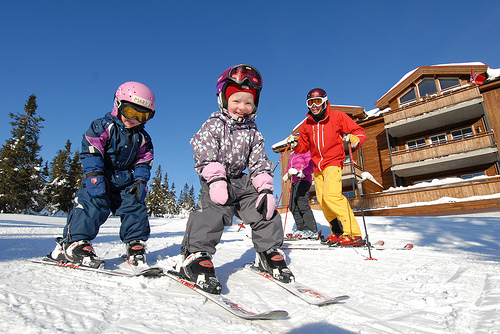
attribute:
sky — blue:
[285, 25, 385, 92]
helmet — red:
[304, 86, 329, 103]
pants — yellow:
[297, 147, 375, 247]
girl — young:
[52, 77, 157, 267]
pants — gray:
[185, 169, 280, 254]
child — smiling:
[176, 65, 295, 292]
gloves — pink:
[201, 159, 278, 221]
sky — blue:
[1, 3, 498, 60]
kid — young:
[183, 67, 295, 287]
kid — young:
[179, 65, 291, 278]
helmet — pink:
[112, 82, 155, 115]